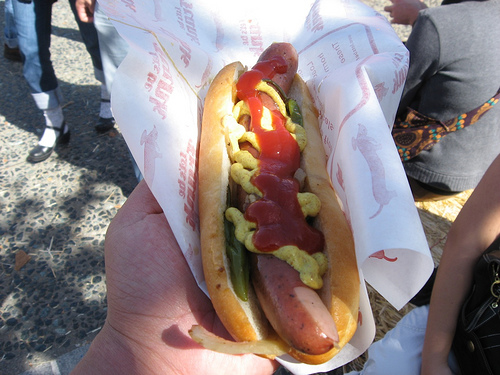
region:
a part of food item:
[188, 25, 359, 330]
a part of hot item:
[167, 63, 362, 361]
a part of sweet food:
[191, 33, 425, 347]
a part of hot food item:
[191, 60, 397, 358]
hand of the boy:
[117, 169, 227, 371]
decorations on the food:
[236, 79, 321, 356]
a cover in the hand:
[317, 26, 437, 293]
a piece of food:
[178, 313, 262, 371]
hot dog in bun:
[253, 44, 340, 356]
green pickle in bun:
[223, 167, 253, 302]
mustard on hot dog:
[226, 77, 327, 287]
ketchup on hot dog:
[237, 56, 321, 253]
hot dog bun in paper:
[198, 62, 362, 363]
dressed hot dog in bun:
[203, 40, 363, 357]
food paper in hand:
[95, 2, 435, 313]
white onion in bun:
[191, 327, 283, 362]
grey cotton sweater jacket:
[408, 4, 499, 190]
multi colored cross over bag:
[394, 86, 498, 156]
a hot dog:
[275, 295, 327, 345]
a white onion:
[218, 332, 243, 353]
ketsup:
[265, 182, 300, 236]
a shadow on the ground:
[40, 277, 90, 321]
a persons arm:
[436, 266, 456, 314]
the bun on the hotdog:
[196, 209, 233, 274]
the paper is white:
[359, 182, 401, 237]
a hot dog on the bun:
[271, 291, 323, 346]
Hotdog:
[190, 41, 363, 361]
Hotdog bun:
[198, 64, 359, 361]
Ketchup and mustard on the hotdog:
[226, 60, 333, 290]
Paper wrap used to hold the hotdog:
[89, 2, 437, 374]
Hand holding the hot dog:
[53, 180, 275, 372]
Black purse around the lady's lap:
[446, 235, 496, 373]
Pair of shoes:
[24, 85, 115, 166]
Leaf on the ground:
[11, 246, 29, 277]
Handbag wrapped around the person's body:
[395, 85, 499, 162]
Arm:
[423, 157, 499, 372]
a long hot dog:
[168, 29, 401, 373]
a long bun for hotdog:
[175, 28, 379, 356]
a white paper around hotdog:
[94, 6, 441, 336]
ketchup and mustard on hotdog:
[208, 29, 345, 314]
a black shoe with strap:
[22, 104, 78, 170]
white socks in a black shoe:
[25, 97, 79, 178]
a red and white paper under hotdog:
[118, 12, 452, 284]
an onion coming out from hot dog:
[172, 302, 319, 374]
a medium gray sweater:
[392, 4, 497, 204]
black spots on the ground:
[2, 146, 119, 323]